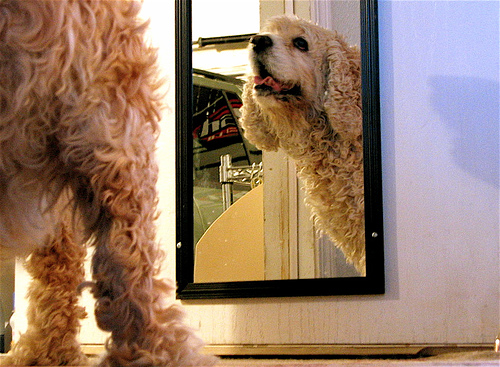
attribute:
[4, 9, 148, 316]
dog — fluffy, tan, reflected, white, furry, happy, curly, refected, blonde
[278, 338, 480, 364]
baseboard — dirty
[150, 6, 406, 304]
mirror — framed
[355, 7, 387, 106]
frame — black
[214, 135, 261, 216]
shelf — chrome, silver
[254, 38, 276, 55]
nose — black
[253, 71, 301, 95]
tongue — pink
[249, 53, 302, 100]
mouth — open